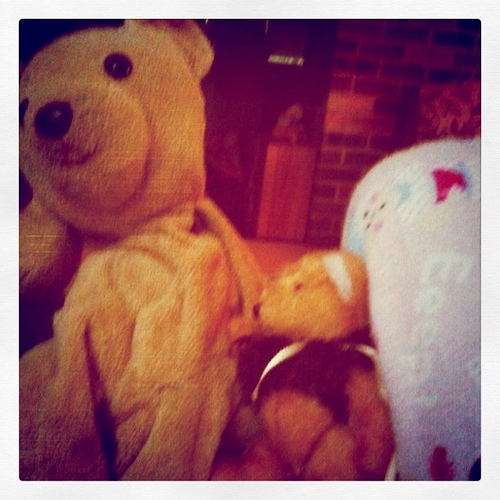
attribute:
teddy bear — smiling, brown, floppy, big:
[20, 22, 261, 481]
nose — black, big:
[34, 102, 74, 140]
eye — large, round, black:
[105, 52, 135, 80]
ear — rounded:
[124, 19, 215, 86]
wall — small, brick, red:
[304, 20, 482, 247]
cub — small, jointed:
[240, 250, 395, 482]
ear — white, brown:
[324, 250, 367, 303]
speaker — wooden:
[242, 138, 319, 242]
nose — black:
[251, 303, 264, 317]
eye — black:
[292, 283, 305, 291]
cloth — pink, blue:
[343, 138, 478, 481]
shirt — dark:
[248, 336, 383, 423]